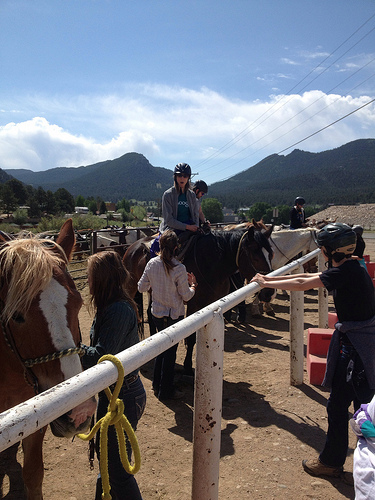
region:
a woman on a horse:
[157, 155, 270, 308]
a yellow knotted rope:
[93, 352, 153, 496]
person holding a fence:
[240, 225, 371, 354]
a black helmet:
[290, 195, 307, 205]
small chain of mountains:
[23, 135, 372, 195]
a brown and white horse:
[2, 225, 100, 456]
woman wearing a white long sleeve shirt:
[138, 256, 191, 321]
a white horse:
[274, 225, 312, 260]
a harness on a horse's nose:
[3, 309, 100, 393]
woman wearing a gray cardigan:
[158, 186, 207, 233]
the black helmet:
[171, 160, 192, 176]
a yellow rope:
[93, 351, 146, 498]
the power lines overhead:
[269, 68, 342, 139]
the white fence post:
[196, 322, 221, 496]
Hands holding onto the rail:
[239, 265, 326, 296]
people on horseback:
[152, 157, 217, 265]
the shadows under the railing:
[220, 369, 299, 474]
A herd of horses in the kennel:
[65, 217, 146, 258]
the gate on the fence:
[77, 233, 97, 279]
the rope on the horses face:
[24, 332, 94, 371]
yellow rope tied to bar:
[73, 356, 143, 497]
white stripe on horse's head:
[27, 271, 91, 399]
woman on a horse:
[160, 162, 202, 236]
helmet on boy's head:
[314, 224, 363, 259]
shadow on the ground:
[154, 367, 329, 461]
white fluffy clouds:
[219, 95, 373, 143]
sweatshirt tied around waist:
[328, 321, 373, 392]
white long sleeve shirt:
[134, 254, 196, 318]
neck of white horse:
[271, 224, 313, 261]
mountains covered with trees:
[1, 149, 373, 183]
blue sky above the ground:
[83, 18, 134, 53]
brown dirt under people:
[239, 446, 286, 480]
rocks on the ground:
[250, 431, 287, 473]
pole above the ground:
[176, 345, 246, 453]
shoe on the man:
[296, 438, 341, 483]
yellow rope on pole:
[91, 379, 152, 461]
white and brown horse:
[15, 279, 92, 361]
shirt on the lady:
[141, 266, 182, 302]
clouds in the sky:
[153, 96, 216, 149]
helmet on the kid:
[301, 205, 362, 277]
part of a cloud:
[177, 81, 207, 111]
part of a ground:
[250, 438, 281, 461]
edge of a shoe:
[295, 458, 329, 485]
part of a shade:
[231, 401, 267, 459]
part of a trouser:
[328, 417, 346, 447]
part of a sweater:
[309, 354, 351, 390]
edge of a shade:
[244, 416, 272, 427]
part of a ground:
[261, 462, 280, 495]